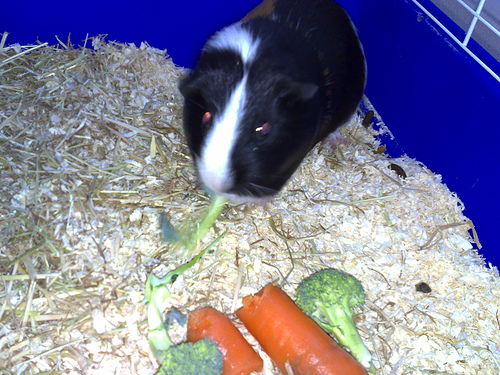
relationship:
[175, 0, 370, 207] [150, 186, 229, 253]
guinea pig eating greens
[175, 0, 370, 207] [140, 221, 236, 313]
guinea pig eating greens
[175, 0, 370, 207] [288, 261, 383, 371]
guinea pig eating greens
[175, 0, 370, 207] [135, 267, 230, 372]
guinea pig eating greens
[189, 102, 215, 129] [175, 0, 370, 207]
eye of guinea pig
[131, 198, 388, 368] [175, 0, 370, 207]
dinner of guinea pig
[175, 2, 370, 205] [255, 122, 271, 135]
animal has eye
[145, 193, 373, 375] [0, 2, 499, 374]
vegetable left in cage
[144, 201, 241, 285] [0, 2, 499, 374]
vegetable left in cage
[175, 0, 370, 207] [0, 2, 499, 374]
guinea pig in cage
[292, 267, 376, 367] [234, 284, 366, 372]
broccoli by carrot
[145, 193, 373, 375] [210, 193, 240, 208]
vegetable in mouth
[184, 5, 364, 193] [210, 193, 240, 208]
gerbil has mouth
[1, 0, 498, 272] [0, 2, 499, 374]
wall on cage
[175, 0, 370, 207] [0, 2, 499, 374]
guinea pig has cage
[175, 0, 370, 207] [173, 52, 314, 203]
guinea pig has head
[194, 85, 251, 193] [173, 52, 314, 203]
stripe on head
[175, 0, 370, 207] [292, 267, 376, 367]
guinea pig eating broccoli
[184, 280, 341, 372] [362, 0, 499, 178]
carrots in cage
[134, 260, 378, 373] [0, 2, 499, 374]
broccoli in cage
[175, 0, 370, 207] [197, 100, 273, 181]
guinea pig has face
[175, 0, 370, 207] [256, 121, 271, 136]
guinea pig has eye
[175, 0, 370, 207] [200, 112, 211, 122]
guinea pig has eye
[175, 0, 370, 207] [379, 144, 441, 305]
guinea pig has poop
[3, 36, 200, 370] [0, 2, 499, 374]
hay in cage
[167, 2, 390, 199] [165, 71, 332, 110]
guinea pig has ears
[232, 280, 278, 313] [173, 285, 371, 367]
bite marks in carrot